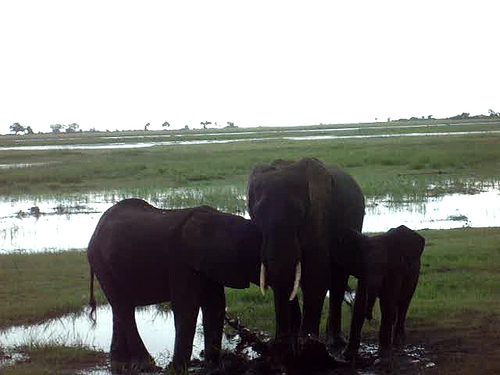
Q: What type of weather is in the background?
A: It is cloudy.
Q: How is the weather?
A: It is cloudy.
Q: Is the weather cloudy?
A: Yes, it is cloudy.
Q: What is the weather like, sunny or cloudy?
A: It is cloudy.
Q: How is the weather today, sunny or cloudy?
A: It is cloudy.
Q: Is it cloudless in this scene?
A: No, it is cloudy.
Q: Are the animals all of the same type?
A: Yes, all the animals are elephants.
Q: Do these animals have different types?
A: No, all the animals are elephants.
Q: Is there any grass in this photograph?
A: Yes, there is grass.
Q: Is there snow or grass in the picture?
A: Yes, there is grass.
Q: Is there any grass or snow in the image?
A: Yes, there is grass.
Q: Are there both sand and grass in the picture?
A: No, there is grass but no sand.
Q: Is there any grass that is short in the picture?
A: Yes, there is short grass.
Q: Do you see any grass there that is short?
A: Yes, there is grass that is short.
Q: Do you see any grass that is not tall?
A: Yes, there is short grass.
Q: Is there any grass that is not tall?
A: Yes, there is short grass.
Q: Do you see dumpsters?
A: No, there are no dumpsters.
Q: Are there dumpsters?
A: No, there are no dumpsters.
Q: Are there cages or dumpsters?
A: No, there are no dumpsters or cages.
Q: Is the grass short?
A: Yes, the grass is short.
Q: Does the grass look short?
A: Yes, the grass is short.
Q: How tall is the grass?
A: The grass is short.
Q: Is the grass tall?
A: No, the grass is short.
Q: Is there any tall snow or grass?
A: No, there is grass but it is short.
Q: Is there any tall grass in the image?
A: No, there is grass but it is short.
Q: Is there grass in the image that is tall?
A: No, there is grass but it is short.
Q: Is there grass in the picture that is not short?
A: No, there is grass but it is short.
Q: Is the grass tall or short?
A: The grass is short.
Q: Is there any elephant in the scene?
A: Yes, there is an elephant.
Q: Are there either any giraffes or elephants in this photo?
A: Yes, there is an elephant.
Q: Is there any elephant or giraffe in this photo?
A: Yes, there is an elephant.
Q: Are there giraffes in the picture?
A: No, there are no giraffes.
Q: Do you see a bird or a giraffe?
A: No, there are no giraffes or birds.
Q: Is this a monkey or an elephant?
A: This is an elephant.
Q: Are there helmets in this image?
A: No, there are no helmets.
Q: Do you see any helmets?
A: No, there are no helmets.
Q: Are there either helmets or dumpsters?
A: No, there are no helmets or dumpsters.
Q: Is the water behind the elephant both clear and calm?
A: Yes, the water is clear and calm.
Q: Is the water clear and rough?
A: No, the water is clear but calm.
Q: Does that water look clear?
A: Yes, the water is clear.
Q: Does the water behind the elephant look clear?
A: Yes, the water is clear.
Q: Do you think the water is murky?
A: No, the water is clear.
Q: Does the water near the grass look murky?
A: No, the water is clear.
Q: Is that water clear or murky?
A: The water is clear.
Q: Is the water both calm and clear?
A: Yes, the water is calm and clear.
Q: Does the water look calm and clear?
A: Yes, the water is calm and clear.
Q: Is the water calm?
A: Yes, the water is calm.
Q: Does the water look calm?
A: Yes, the water is calm.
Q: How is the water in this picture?
A: The water is calm.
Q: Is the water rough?
A: No, the water is calm.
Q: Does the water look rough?
A: No, the water is calm.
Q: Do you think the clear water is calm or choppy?
A: The water is calm.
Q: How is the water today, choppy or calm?
A: The water is calm.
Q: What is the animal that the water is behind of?
A: The animal is an elephant.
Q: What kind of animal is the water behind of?
A: The water is behind the elephant.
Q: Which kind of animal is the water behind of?
A: The water is behind the elephant.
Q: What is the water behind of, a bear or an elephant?
A: The water is behind an elephant.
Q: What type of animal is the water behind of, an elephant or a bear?
A: The water is behind an elephant.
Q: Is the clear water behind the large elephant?
A: Yes, the water is behind the elephant.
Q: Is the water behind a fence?
A: No, the water is behind the elephant.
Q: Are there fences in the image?
A: No, there are no fences.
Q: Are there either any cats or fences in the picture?
A: No, there are no fences or cats.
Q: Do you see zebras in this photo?
A: No, there are no zebras.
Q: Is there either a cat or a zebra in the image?
A: No, there are no zebras or cats.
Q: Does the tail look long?
A: Yes, the tail is long.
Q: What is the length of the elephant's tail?
A: The tail is long.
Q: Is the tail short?
A: No, the tail is long.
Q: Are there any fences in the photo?
A: No, there are no fences.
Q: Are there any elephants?
A: Yes, there is an elephant.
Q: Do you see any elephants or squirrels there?
A: Yes, there is an elephant.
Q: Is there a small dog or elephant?
A: Yes, there is a small elephant.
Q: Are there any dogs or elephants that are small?
A: Yes, the elephant is small.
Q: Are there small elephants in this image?
A: Yes, there is a small elephant.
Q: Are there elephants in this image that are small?
A: Yes, there is an elephant that is small.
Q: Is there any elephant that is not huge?
A: Yes, there is a small elephant.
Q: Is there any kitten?
A: No, there are no kittens.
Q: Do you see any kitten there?
A: No, there are no kittens.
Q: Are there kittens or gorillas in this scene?
A: No, there are no kittens or gorillas.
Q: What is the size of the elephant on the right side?
A: The elephant is small.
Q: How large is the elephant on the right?
A: The elephant is small.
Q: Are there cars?
A: No, there are no cars.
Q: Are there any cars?
A: No, there are no cars.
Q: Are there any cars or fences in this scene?
A: No, there are no cars or fences.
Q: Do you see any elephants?
A: Yes, there is an elephant.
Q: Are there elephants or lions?
A: Yes, there is an elephant.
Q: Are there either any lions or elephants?
A: Yes, there is an elephant.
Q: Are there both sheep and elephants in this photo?
A: No, there is an elephant but no sheep.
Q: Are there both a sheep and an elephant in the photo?
A: No, there is an elephant but no sheep.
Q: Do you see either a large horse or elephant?
A: Yes, there is a large elephant.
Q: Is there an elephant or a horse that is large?
A: Yes, the elephant is large.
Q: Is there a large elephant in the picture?
A: Yes, there is a large elephant.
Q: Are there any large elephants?
A: Yes, there is a large elephant.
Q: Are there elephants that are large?
A: Yes, there is an elephant that is large.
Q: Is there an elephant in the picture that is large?
A: Yes, there is an elephant that is large.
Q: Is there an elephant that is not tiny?
A: Yes, there is a large elephant.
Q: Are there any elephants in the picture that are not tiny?
A: Yes, there is a large elephant.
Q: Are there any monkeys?
A: No, there are no monkeys.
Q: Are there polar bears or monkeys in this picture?
A: No, there are no monkeys or polar bears.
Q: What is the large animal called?
A: The animal is an elephant.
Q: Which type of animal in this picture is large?
A: The animal is an elephant.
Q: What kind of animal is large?
A: The animal is an elephant.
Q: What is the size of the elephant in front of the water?
A: The elephant is large.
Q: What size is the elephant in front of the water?
A: The elephant is large.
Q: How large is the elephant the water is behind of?
A: The elephant is large.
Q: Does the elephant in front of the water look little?
A: No, the elephant is large.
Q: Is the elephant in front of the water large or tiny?
A: The elephant is large.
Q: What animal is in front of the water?
A: The elephant is in front of the water.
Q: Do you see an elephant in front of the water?
A: Yes, there is an elephant in front of the water.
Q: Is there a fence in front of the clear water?
A: No, there is an elephant in front of the water.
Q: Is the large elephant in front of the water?
A: Yes, the elephant is in front of the water.